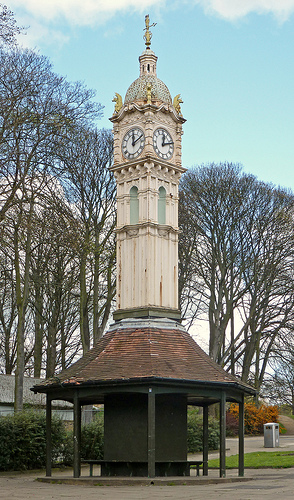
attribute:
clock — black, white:
[121, 128, 147, 160]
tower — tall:
[108, 15, 187, 321]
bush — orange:
[225, 402, 280, 437]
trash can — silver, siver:
[263, 421, 281, 448]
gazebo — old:
[30, 319, 258, 485]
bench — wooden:
[78, 458, 204, 476]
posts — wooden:
[45, 389, 245, 479]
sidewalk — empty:
[1, 410, 293, 499]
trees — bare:
[0, 1, 293, 409]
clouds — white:
[0, 1, 292, 406]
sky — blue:
[0, 2, 293, 408]